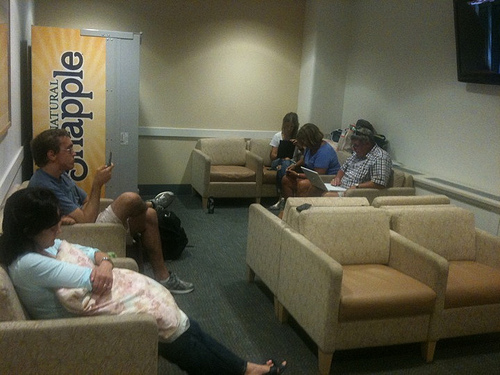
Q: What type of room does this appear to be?
A: A waiting room.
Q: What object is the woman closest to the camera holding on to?
A: A pillow.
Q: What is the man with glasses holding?
A: A cell phone.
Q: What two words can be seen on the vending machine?
A: Natural Snapple.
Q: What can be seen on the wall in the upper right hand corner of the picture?
A: Television.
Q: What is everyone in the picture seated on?
A: Chairs.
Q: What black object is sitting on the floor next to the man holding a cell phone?
A: A backpack.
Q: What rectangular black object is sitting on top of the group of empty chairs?
A: Television remote.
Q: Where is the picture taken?
A: A waiting room.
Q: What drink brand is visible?
A: Snapple.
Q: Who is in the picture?
A: A man and women.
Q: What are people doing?
A: Sitting.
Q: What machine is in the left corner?
A: Vending.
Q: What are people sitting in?
A: Chairs.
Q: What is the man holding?
A: A phone.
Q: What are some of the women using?
A: Computers.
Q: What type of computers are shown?
A: Laptops.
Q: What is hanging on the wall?
A: A television.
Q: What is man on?
A: Cell phone.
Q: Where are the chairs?
A: Waiting room.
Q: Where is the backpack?
A: On floor.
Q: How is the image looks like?
A: Good.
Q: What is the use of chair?
A: Sit.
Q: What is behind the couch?
A: Wall.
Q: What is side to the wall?
A: Vending machine.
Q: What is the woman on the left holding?
A: A pillow.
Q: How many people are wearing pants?
A: Two.